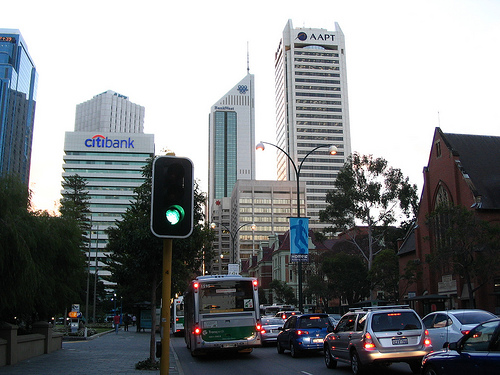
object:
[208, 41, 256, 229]
building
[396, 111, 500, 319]
building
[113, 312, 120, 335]
person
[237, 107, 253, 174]
wall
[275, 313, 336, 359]
car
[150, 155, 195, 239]
light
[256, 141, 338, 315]
pole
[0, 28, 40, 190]
building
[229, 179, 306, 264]
building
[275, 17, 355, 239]
building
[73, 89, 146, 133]
building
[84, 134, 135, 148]
logo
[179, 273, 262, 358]
bus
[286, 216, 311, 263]
banner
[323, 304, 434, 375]
car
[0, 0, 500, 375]
city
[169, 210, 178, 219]
greenlight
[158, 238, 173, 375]
yellow pole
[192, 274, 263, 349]
back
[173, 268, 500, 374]
traffic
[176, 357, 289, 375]
pavement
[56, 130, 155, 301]
building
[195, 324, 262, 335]
lights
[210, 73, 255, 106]
top